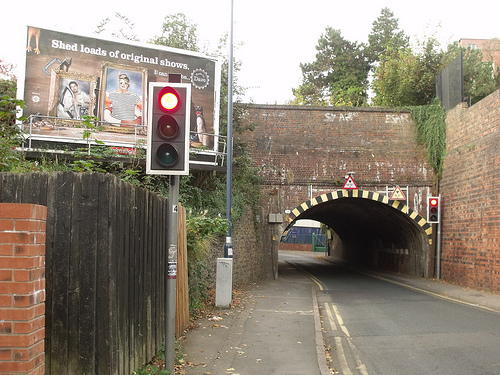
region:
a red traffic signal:
[119, 75, 212, 193]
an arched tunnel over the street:
[253, 174, 447, 298]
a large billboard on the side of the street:
[13, 21, 227, 198]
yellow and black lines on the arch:
[271, 176, 433, 246]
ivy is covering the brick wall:
[377, 95, 472, 181]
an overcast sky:
[245, 41, 295, 95]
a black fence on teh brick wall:
[423, 57, 472, 115]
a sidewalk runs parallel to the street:
[235, 266, 319, 372]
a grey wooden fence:
[53, 190, 160, 368]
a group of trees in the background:
[291, 8, 437, 101]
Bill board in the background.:
[18, 18, 343, 178]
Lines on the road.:
[274, 272, 324, 334]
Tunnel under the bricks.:
[259, 145, 451, 321]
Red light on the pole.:
[406, 160, 474, 310]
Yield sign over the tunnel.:
[315, 142, 445, 219]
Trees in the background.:
[242, 2, 469, 118]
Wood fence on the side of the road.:
[68, 150, 278, 365]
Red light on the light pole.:
[135, 66, 197, 118]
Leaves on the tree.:
[191, 293, 271, 354]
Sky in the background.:
[211, 7, 398, 109]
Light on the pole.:
[127, 41, 237, 243]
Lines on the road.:
[287, 257, 429, 371]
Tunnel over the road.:
[283, 160, 452, 300]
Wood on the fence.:
[42, 152, 267, 371]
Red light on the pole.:
[145, 70, 192, 238]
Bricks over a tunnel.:
[247, 77, 395, 204]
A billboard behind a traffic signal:
[9, 11, 229, 184]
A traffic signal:
[138, 69, 201, 373]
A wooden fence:
[7, 165, 163, 371]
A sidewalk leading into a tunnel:
[206, 167, 338, 371]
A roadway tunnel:
[262, 166, 452, 337]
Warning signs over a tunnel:
[271, 162, 445, 304]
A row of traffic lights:
[143, 77, 195, 178]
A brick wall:
[440, 95, 496, 295]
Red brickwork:
[0, 202, 50, 373]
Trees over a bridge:
[237, 5, 438, 172]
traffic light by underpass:
[424, 194, 443, 226]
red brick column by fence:
[1, 203, 42, 369]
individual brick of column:
[15, 296, 31, 307]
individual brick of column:
[15, 270, 31, 279]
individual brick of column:
[18, 245, 30, 258]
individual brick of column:
[4, 232, 26, 239]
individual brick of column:
[1, 202, 30, 217]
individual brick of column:
[3, 333, 26, 348]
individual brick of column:
[26, 321, 41, 330]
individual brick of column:
[0, 270, 12, 280]